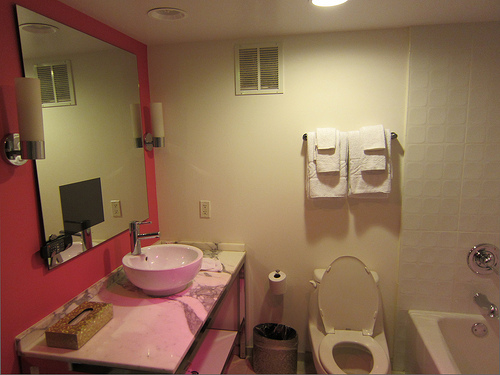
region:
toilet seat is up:
[314, 255, 384, 328]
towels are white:
[304, 126, 396, 194]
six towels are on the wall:
[302, 114, 398, 217]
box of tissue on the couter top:
[63, 276, 118, 352]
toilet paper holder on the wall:
[253, 263, 294, 305]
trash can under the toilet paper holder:
[255, 319, 295, 372]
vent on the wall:
[231, 46, 313, 102]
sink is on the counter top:
[113, 216, 210, 316]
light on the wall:
[9, 75, 49, 186]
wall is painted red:
[4, 230, 61, 329]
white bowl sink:
[124, 241, 204, 294]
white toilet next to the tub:
[302, 251, 398, 373]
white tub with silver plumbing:
[401, 234, 498, 374]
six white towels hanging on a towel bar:
[299, 121, 401, 205]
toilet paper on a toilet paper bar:
[264, 262, 290, 299]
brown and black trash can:
[249, 317, 299, 374]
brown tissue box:
[40, 296, 119, 351]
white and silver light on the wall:
[2, 74, 49, 176]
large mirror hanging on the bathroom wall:
[9, 3, 153, 275]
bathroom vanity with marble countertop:
[7, 234, 252, 368]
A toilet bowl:
[341, 302, 368, 362]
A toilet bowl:
[336, 271, 363, 371]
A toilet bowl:
[316, 294, 349, 354]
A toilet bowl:
[328, 319, 349, 366]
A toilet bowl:
[337, 313, 354, 363]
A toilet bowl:
[317, 255, 345, 372]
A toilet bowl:
[324, 266, 355, 362]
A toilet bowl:
[300, 251, 340, 369]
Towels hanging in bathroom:
[298, 113, 349, 213]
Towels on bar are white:
[301, 120, 349, 215]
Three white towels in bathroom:
[295, 120, 351, 227]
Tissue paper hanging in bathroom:
[268, 259, 292, 309]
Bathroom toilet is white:
[307, 242, 403, 373]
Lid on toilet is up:
[293, 241, 386, 373]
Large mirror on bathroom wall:
[12, 4, 174, 264]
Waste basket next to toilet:
[249, 312, 347, 373]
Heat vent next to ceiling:
[218, 35, 328, 113]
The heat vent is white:
[228, 38, 310, 108]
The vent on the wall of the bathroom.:
[230, 45, 283, 95]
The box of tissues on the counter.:
[38, 306, 118, 346]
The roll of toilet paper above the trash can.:
[264, 260, 295, 299]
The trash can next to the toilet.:
[249, 314, 299, 374]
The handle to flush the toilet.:
[306, 275, 317, 288]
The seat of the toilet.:
[319, 324, 387, 374]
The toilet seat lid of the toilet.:
[318, 249, 383, 339]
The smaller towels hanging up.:
[312, 126, 389, 153]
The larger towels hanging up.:
[300, 135, 391, 201]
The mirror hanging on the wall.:
[20, 39, 156, 269]